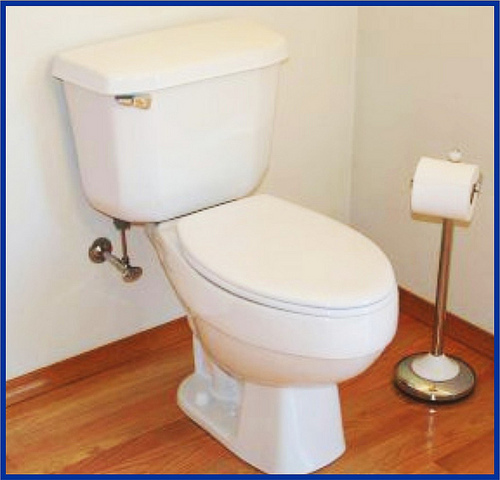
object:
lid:
[175, 192, 400, 311]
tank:
[48, 18, 292, 225]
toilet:
[51, 24, 401, 479]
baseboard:
[6, 316, 191, 407]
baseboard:
[397, 284, 493, 360]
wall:
[352, 6, 496, 358]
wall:
[5, 6, 358, 409]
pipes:
[85, 215, 145, 284]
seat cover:
[175, 197, 399, 314]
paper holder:
[392, 217, 476, 408]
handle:
[114, 90, 155, 110]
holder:
[388, 146, 489, 406]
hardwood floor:
[7, 308, 493, 476]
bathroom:
[6, 6, 494, 479]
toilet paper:
[409, 151, 482, 225]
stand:
[387, 146, 479, 403]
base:
[410, 350, 464, 383]